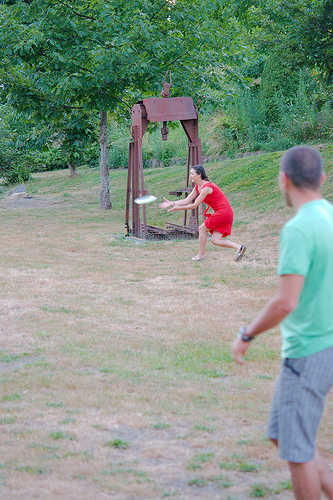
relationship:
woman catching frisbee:
[176, 167, 233, 246] [136, 193, 159, 212]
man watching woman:
[263, 160, 333, 357] [176, 167, 233, 246]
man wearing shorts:
[263, 160, 333, 357] [287, 353, 320, 465]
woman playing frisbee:
[176, 167, 233, 246] [136, 193, 159, 212]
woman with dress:
[176, 167, 233, 246] [207, 190, 230, 221]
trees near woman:
[181, 23, 294, 120] [176, 167, 233, 246]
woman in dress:
[176, 167, 233, 246] [207, 190, 230, 221]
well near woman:
[130, 78, 201, 141] [176, 167, 233, 246]